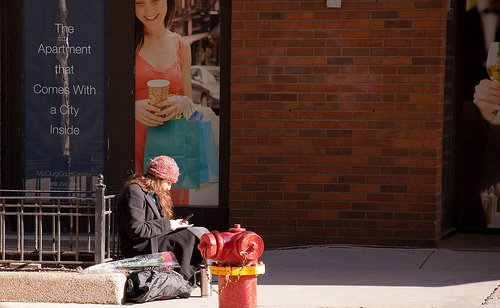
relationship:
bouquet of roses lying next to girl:
[80, 250, 189, 276] [116, 154, 206, 292]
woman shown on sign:
[131, 0, 196, 207] [134, 0, 217, 209]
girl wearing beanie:
[116, 154, 206, 292] [145, 155, 180, 183]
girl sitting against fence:
[116, 154, 206, 292] [2, 171, 125, 269]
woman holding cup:
[131, 0, 196, 204] [145, 79, 170, 112]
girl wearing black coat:
[116, 154, 206, 292] [111, 183, 210, 278]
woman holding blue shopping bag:
[131, 0, 196, 204] [141, 121, 225, 194]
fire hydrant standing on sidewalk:
[197, 222, 267, 305] [179, 228, 495, 305]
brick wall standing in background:
[232, 6, 456, 247] [2, 2, 479, 244]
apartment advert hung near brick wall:
[9, 0, 113, 213] [232, 6, 456, 247]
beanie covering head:
[145, 155, 180, 183] [146, 161, 176, 191]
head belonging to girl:
[146, 161, 176, 191] [116, 154, 206, 292]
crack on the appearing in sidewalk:
[414, 243, 443, 271] [2, 234, 484, 305]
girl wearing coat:
[116, 154, 206, 292] [113, 178, 200, 276]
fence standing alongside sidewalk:
[2, 171, 125, 269] [2, 234, 484, 305]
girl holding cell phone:
[116, 154, 206, 292] [176, 211, 195, 222]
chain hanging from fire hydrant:
[224, 253, 248, 283] [197, 222, 267, 305]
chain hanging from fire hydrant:
[204, 252, 250, 294] [197, 222, 267, 305]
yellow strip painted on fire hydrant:
[202, 263, 272, 276] [197, 222, 267, 305]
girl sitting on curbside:
[116, 154, 206, 292] [7, 274, 131, 305]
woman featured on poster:
[131, 0, 196, 204] [130, 1, 223, 202]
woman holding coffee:
[131, 0, 196, 204] [144, 75, 170, 115]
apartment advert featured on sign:
[9, 0, 223, 213] [134, 0, 217, 209]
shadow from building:
[198, 241, 498, 284] [0, 2, 500, 250]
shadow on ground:
[198, 241, 498, 284] [1, 242, 498, 305]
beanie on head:
[147, 152, 178, 183] [143, 156, 180, 193]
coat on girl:
[113, 179, 200, 276] [116, 154, 206, 292]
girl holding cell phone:
[122, 154, 206, 292] [182, 213, 194, 223]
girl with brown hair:
[116, 154, 206, 292] [119, 170, 174, 219]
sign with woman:
[134, 0, 217, 209] [131, 0, 196, 204]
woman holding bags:
[131, 0, 196, 204] [138, 94, 220, 190]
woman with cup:
[131, 0, 196, 204] [146, 74, 169, 119]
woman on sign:
[131, 0, 196, 204] [134, 0, 217, 209]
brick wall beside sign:
[232, 6, 456, 247] [131, 2, 224, 206]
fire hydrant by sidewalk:
[197, 222, 267, 305] [2, 243, 498, 305]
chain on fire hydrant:
[204, 252, 250, 294] [197, 222, 267, 305]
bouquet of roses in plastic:
[80, 253, 189, 283] [80, 249, 181, 275]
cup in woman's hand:
[145, 77, 173, 113] [134, 79, 198, 131]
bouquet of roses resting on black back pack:
[80, 250, 189, 276] [124, 268, 195, 303]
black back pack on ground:
[124, 268, 195, 296] [1, 242, 498, 305]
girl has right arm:
[116, 154, 206, 292] [116, 181, 192, 241]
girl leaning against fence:
[116, 154, 206, 292] [2, 171, 125, 269]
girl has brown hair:
[116, 154, 206, 292] [119, 170, 181, 218]